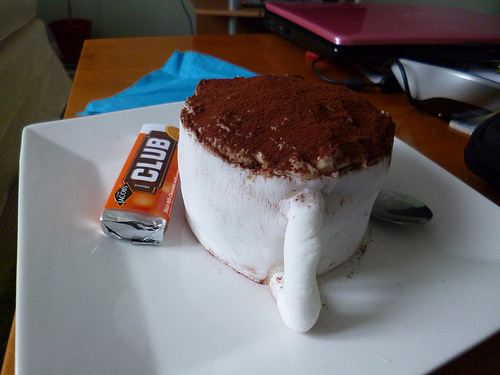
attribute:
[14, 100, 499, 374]
plate — white, square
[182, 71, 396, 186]
chocolate powder — overflowing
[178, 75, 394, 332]
cup — marshmallow, dessert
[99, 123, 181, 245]
bar — wrapped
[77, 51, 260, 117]
napkin — blue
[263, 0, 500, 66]
laptop — pink, closed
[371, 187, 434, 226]
spoon — silver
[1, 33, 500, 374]
table — wooden, brown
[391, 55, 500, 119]
mouse — silver, black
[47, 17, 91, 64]
flower pot — dark